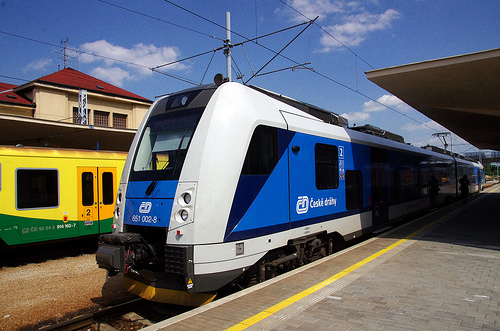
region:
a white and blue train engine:
[95, 79, 454, 308]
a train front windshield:
[130, 105, 202, 171]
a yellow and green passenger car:
[0, 147, 127, 254]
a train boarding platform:
[139, 175, 499, 329]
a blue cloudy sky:
[0, 0, 499, 155]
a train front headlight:
[178, 191, 190, 203]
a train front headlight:
[178, 208, 187, 219]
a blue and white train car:
[454, 152, 486, 192]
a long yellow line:
[225, 185, 497, 330]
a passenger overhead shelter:
[363, 47, 499, 149]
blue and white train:
[98, 123, 480, 292]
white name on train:
[289, 186, 359, 218]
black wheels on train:
[229, 227, 369, 297]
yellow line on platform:
[249, 212, 401, 327]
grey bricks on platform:
[366, 214, 498, 314]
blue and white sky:
[79, 3, 366, 78]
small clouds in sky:
[66, 18, 413, 114]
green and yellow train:
[4, 116, 135, 253]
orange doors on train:
[76, 167, 126, 222]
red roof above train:
[41, 73, 143, 91]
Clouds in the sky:
[275, 0, 395, 57]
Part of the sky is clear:
[407, 1, 494, 43]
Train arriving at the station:
[95, 75, 481, 305]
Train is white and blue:
[97, 73, 482, 301]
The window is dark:
[312, 144, 339, 190]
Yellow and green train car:
[0, 146, 128, 244]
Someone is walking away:
[458, 172, 468, 199]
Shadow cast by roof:
[347, 129, 497, 250]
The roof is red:
[37, 66, 149, 98]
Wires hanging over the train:
[2, 1, 474, 156]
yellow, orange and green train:
[0, 145, 126, 273]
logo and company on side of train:
[288, 188, 355, 220]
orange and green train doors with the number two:
[75, 160, 121, 247]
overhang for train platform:
[358, 50, 498, 146]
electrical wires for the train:
[101, 1, 358, 116]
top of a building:
[1, 60, 152, 129]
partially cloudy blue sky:
[1, 0, 388, 77]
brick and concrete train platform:
[162, 248, 491, 327]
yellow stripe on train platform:
[206, 248, 394, 326]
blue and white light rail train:
[117, 86, 484, 300]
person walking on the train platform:
[459, 175, 469, 197]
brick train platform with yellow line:
[135, 182, 498, 329]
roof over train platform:
[365, 38, 495, 159]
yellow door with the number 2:
[80, 169, 117, 235]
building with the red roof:
[2, 67, 150, 128]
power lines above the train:
[15, 5, 372, 82]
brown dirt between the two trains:
[5, 256, 107, 320]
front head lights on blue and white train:
[115, 187, 192, 221]